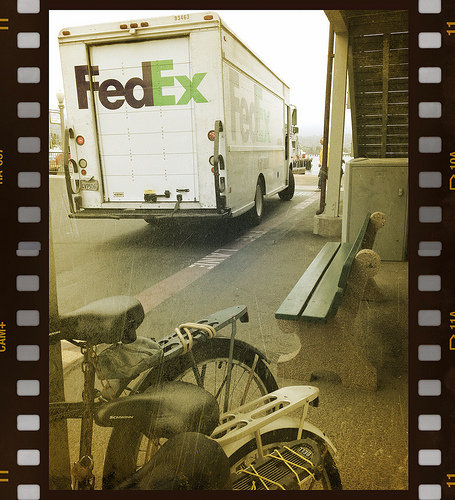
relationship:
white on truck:
[114, 126, 183, 174] [56, 35, 258, 247]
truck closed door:
[56, 35, 258, 247] [85, 48, 196, 231]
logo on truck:
[61, 63, 211, 127] [56, 35, 258, 247]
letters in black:
[75, 73, 158, 111] [77, 76, 84, 97]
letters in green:
[75, 73, 158, 111] [161, 62, 172, 70]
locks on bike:
[174, 323, 210, 346] [58, 316, 263, 389]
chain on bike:
[69, 358, 96, 412] [58, 316, 263, 389]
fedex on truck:
[61, 63, 211, 127] [56, 35, 258, 247]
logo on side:
[228, 78, 281, 163] [216, 27, 300, 214]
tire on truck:
[248, 173, 269, 229] [56, 35, 258, 247]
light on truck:
[68, 129, 224, 152] [56, 35, 258, 247]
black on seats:
[147, 402, 170, 416] [65, 310, 193, 439]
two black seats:
[62, 302, 131, 443] [65, 310, 193, 439]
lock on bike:
[70, 460, 99, 483] [58, 316, 263, 389]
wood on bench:
[290, 290, 330, 311] [286, 229, 381, 323]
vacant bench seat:
[281, 232, 330, 351] [302, 257, 349, 289]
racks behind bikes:
[178, 316, 305, 428] [73, 313, 310, 482]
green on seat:
[161, 62, 172, 70] [302, 257, 349, 289]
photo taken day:
[42, 11, 454, 487] [251, 22, 318, 46]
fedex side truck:
[228, 78, 281, 163] [56, 35, 258, 247]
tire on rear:
[237, 181, 272, 243] [111, 196, 258, 243]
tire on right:
[275, 165, 311, 199] [281, 161, 298, 217]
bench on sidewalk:
[286, 229, 381, 323] [257, 240, 280, 307]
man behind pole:
[320, 128, 327, 175] [323, 34, 331, 214]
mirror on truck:
[289, 98, 298, 147] [56, 35, 258, 247]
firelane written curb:
[192, 211, 284, 291] [131, 221, 296, 264]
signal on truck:
[202, 127, 218, 164] [56, 35, 258, 247]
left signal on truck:
[72, 129, 88, 161] [56, 35, 258, 247]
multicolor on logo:
[74, 86, 202, 100] [72, 59, 206, 114]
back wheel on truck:
[119, 174, 278, 219] [56, 35, 258, 247]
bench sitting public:
[286, 229, 381, 323] [271, 203, 393, 374]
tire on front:
[275, 173, 296, 203] [272, 77, 314, 216]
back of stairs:
[353, 24, 409, 150] [352, 30, 412, 49]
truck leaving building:
[56, 35, 258, 247] [285, 16, 415, 406]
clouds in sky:
[248, 34, 330, 63] [251, 22, 318, 46]